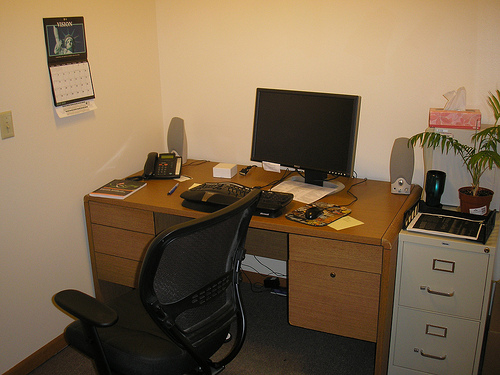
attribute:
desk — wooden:
[80, 150, 420, 371]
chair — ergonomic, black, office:
[52, 195, 262, 372]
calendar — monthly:
[41, 15, 101, 117]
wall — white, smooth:
[158, 4, 495, 199]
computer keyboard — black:
[182, 180, 292, 220]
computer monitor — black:
[249, 80, 359, 209]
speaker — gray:
[386, 137, 415, 200]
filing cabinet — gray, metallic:
[391, 200, 497, 372]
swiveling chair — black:
[53, 186, 263, 372]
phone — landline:
[142, 153, 182, 183]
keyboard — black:
[182, 183, 290, 216]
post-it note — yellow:
[326, 213, 352, 247]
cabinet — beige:
[386, 206, 495, 373]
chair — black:
[37, 237, 257, 360]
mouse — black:
[302, 199, 327, 226]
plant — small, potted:
[401, 88, 499, 180]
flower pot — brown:
[455, 183, 493, 206]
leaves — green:
[406, 123, 498, 179]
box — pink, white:
[422, 104, 483, 133]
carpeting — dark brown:
[15, 335, 367, 367]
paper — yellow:
[326, 208, 364, 235]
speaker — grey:
[382, 132, 418, 195]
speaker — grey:
[161, 108, 193, 164]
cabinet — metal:
[386, 192, 491, 373]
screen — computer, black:
[247, 84, 359, 179]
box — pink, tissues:
[428, 91, 484, 131]